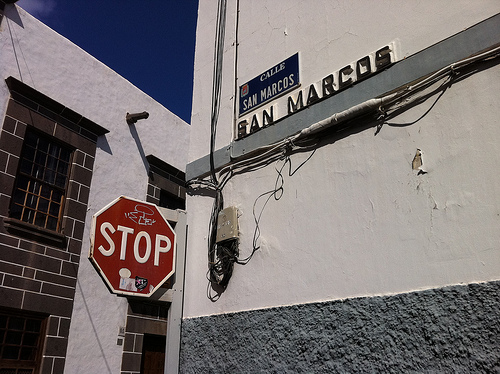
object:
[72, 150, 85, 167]
brick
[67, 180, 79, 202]
brick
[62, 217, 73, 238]
brick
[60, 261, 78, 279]
brick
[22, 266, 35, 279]
brick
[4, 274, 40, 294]
brick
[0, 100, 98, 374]
brick wall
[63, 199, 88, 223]
brick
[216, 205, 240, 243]
electronic device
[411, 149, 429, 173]
damage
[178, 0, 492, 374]
building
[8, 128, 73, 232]
railing.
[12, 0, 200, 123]
sky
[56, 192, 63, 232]
bars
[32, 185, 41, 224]
bars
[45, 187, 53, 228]
bars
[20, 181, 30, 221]
bars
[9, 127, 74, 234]
window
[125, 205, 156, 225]
graffiti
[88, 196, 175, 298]
red sign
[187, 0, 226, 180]
border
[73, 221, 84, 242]
brick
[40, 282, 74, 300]
brick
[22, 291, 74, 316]
brick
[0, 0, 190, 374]
building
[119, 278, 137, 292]
stickers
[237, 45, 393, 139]
letters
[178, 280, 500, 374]
stucco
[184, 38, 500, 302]
wires